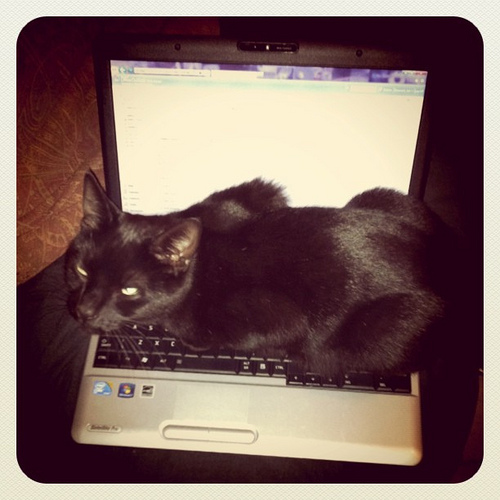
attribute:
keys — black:
[108, 323, 164, 363]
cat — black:
[53, 166, 496, 402]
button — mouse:
[162, 424, 264, 445]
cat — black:
[53, 158, 472, 409]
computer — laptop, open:
[46, 31, 447, 472]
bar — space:
[172, 355, 241, 376]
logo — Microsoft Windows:
[117, 381, 133, 405]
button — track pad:
[168, 421, 268, 452]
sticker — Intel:
[92, 376, 113, 397]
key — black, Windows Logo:
[133, 351, 153, 371]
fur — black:
[226, 221, 367, 321]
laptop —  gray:
[84, 378, 444, 471]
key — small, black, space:
[172, 353, 239, 376]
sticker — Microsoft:
[117, 381, 137, 399]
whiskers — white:
[114, 314, 172, 384]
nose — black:
[78, 305, 100, 321]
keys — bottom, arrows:
[282, 369, 339, 389]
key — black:
[89, 349, 123, 369]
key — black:
[93, 332, 125, 352]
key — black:
[115, 350, 138, 370]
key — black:
[134, 351, 154, 370]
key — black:
[150, 350, 174, 370]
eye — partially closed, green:
[75, 265, 87, 279]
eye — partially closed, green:
[116, 285, 139, 296]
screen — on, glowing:
[110, 58, 428, 215]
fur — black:
[60, 162, 480, 382]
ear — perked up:
[144, 213, 204, 275]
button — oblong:
[161, 423, 255, 444]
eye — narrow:
[75, 263, 88, 277]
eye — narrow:
[116, 284, 139, 295]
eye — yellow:
[118, 281, 143, 301]